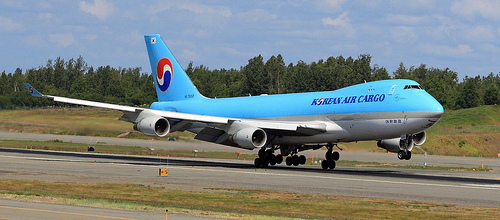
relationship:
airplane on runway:
[12, 31, 448, 168] [20, 132, 439, 179]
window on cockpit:
[403, 82, 415, 90] [394, 75, 431, 104]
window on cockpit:
[414, 83, 426, 92] [394, 75, 431, 104]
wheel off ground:
[397, 147, 412, 160] [2, 109, 497, 219]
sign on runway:
[159, 167, 168, 177] [225, 161, 497, 209]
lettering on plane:
[310, 92, 385, 104] [22, 30, 451, 174]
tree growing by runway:
[73, 55, 86, 85] [1, 137, 498, 208]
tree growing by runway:
[245, 55, 266, 95] [1, 137, 498, 208]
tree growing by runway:
[275, 54, 284, 90] [1, 137, 498, 208]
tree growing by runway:
[292, 60, 310, 89] [1, 137, 498, 208]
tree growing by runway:
[325, 56, 337, 86] [1, 137, 498, 208]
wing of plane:
[43, 60, 264, 176] [22, 30, 451, 174]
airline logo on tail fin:
[155, 56, 171, 91] [142, 33, 202, 98]